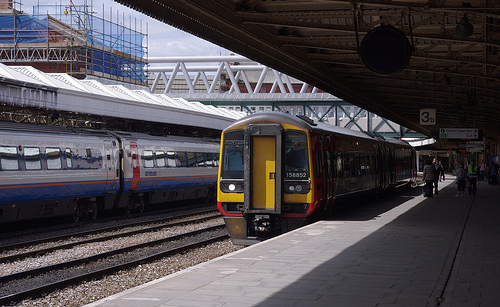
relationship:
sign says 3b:
[416, 105, 438, 128] [420, 111, 435, 127]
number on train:
[281, 168, 313, 183] [213, 114, 418, 246]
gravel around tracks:
[2, 205, 237, 307] [2, 198, 230, 304]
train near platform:
[213, 114, 418, 246] [86, 180, 496, 305]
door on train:
[244, 133, 279, 215] [213, 114, 418, 246]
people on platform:
[418, 152, 500, 204] [86, 180, 496, 305]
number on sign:
[281, 168, 313, 183] [416, 105, 438, 128]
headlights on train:
[223, 183, 241, 192] [213, 114, 418, 246]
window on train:
[140, 152, 158, 170] [213, 114, 418, 246]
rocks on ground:
[2, 205, 237, 307] [2, 173, 492, 303]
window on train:
[140, 152, 158, 170] [1, 121, 226, 222]